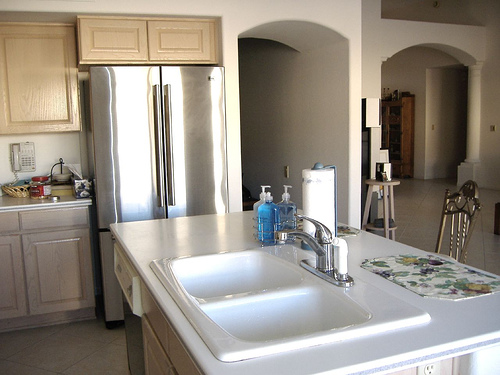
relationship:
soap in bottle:
[249, 194, 297, 245] [250, 193, 280, 242]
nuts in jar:
[26, 175, 51, 197] [31, 174, 52, 199]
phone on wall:
[11, 141, 36, 171] [1, 130, 88, 182]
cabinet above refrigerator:
[78, 15, 219, 65] [79, 62, 269, 329]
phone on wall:
[11, 141, 36, 171] [0, 4, 367, 349]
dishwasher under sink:
[104, 251, 155, 364] [151, 238, 443, 358]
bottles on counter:
[251, 187, 292, 238] [107, 200, 497, 338]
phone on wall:
[11, 145, 36, 170] [41, 138, 56, 152]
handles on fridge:
[150, 82, 176, 209] [87, 65, 238, 323]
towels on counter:
[298, 169, 331, 243] [99, 215, 498, 365]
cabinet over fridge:
[78, 15, 219, 65] [87, 67, 238, 212]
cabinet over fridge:
[78, 15, 150, 61] [87, 67, 238, 212]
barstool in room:
[364, 178, 401, 241] [360, 0, 499, 262]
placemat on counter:
[392, 246, 486, 300] [156, 211, 487, 323]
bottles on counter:
[253, 185, 296, 243] [194, 198, 240, 264]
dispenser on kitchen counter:
[300, 162, 337, 250] [112, 204, 498, 374]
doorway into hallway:
[236, 19, 353, 214] [242, 32, 335, 193]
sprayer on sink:
[327, 231, 351, 278] [137, 239, 437, 367]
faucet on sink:
[272, 212, 355, 286] [137, 239, 437, 367]